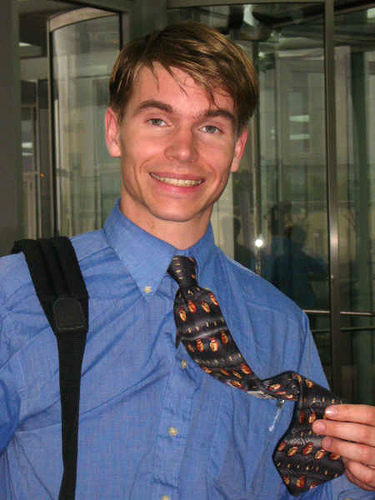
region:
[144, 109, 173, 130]
eye of a person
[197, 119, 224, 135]
eye of a person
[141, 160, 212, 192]
mouth of a person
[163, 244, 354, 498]
tie with design on it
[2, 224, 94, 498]
black shoulder strap over shoulder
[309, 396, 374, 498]
hand of a person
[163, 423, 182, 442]
white button on blue shirt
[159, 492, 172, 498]
white button on blue shirt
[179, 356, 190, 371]
white button on blue shirt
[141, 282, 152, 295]
white button on blue shirt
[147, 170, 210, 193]
A man's smile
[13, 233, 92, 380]
A black backpack strap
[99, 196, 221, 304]
A man's blue shirt collar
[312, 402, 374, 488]
A man's fingers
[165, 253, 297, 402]
A man's necktie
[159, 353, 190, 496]
Buttons on a blue shirt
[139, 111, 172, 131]
One eye of a man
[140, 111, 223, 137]
A man's blue eyes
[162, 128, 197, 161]
A man's nose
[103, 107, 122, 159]
A man's left ear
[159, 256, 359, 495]
man is wearing tie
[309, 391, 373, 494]
left hand is holding end of tie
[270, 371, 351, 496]
end of tie is in left hand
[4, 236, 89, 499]
backpack strap across shoulder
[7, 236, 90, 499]
backpack strap is balck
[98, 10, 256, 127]
man has short hair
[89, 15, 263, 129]
man has brown hair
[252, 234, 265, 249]
light reflecting in door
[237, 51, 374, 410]
door reflecting people front of man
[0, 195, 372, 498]
man's shirt is blue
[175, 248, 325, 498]
Man's brown silk tie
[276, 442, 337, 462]
Orange designs on tie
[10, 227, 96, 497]
Black bag strap on man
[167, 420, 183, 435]
Small white button on shirt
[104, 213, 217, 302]
Sharply creased shirt collar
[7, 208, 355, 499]
Light blue shirt on man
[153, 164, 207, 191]
Smiling mouth on man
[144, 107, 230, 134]
Blue eyes on man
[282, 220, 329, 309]
Reflection of woman in glass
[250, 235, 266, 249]
Round light reflection in glass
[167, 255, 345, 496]
a black neck tie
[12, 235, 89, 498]
a black shoulder strap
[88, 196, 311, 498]
a blue dress shirt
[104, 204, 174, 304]
a button down collar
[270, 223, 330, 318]
a reflection of someone on the window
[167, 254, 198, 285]
a standard tie knot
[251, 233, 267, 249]
a reflection of a light source on the window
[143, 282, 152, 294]
the plastic shirt button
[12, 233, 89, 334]
the cushioned shoulder strap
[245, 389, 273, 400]
the neck tie label brand logo